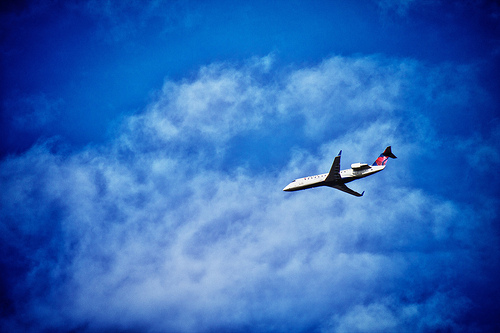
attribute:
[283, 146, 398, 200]
airplane — flying, high, airborne, white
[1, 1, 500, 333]
sky — blue, bright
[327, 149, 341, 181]
wing — dark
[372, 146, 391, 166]
tail — red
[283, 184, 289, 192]
nose — white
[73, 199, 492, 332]
clouds — white, puffy